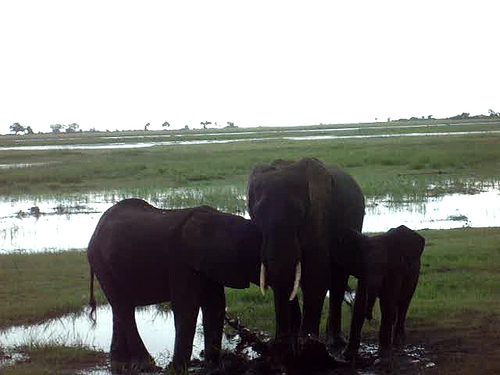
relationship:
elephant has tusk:
[252, 166, 348, 359] [291, 262, 307, 305]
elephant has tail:
[91, 200, 253, 369] [83, 268, 102, 320]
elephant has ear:
[91, 200, 253, 369] [180, 211, 252, 289]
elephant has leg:
[252, 166, 348, 359] [303, 283, 322, 347]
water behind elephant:
[41, 225, 60, 237] [252, 166, 348, 359]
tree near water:
[11, 120, 22, 133] [41, 225, 60, 237]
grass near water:
[458, 289, 479, 308] [41, 225, 60, 237]